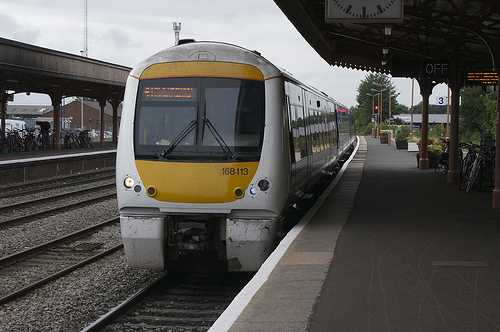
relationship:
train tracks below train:
[107, 274, 216, 326] [95, 26, 296, 280]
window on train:
[134, 86, 266, 156] [115, 40, 356, 271]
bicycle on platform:
[459, 140, 486, 194] [203, 135, 497, 330]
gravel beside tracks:
[2, 245, 147, 330] [2, 176, 125, 325]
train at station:
[115, 40, 356, 271] [222, 0, 498, 330]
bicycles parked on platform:
[8, 105, 103, 167] [0, 139, 115, 188]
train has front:
[115, 40, 356, 271] [113, 33, 287, 265]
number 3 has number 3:
[438, 97, 442, 104] [438, 93, 443, 108]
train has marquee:
[115, 40, 356, 271] [134, 70, 215, 120]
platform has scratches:
[203, 135, 497, 330] [365, 208, 499, 329]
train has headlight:
[115, 40, 356, 271] [119, 175, 137, 191]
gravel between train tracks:
[0, 177, 157, 330] [107, 274, 216, 326]